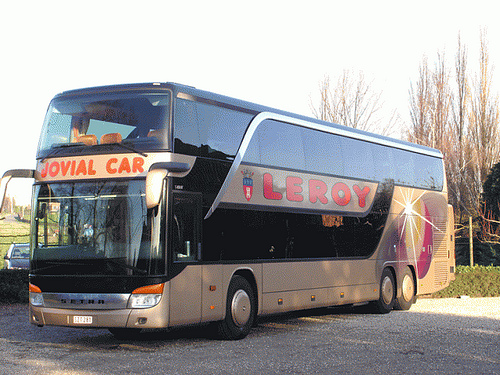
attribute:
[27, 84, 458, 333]
bus — black, brown, double decker, in foreground, parked, side view, gold, large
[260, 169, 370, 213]
word leroy — red, orange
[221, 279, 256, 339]
tire — black, round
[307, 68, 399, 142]
tree — in background, tall, bare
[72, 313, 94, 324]
license plate — white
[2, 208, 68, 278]
grass — patchy, green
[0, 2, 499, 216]
sky — white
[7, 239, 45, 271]
car — in background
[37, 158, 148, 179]
jovial car — orange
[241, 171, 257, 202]
design — red, blue, white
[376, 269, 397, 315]
tire — in back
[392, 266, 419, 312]
tire — in back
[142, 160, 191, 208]
side mirror — gold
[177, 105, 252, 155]
side window — on top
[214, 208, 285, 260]
passenger window — on bottom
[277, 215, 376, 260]
passenger window — on bottom